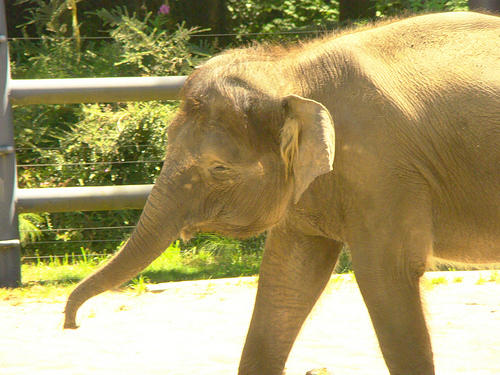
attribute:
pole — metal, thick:
[0, 3, 23, 285]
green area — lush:
[5, 2, 468, 291]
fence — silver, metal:
[0, 3, 184, 288]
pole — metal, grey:
[74, 62, 139, 110]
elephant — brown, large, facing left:
[62, 11, 499, 373]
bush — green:
[17, 51, 202, 265]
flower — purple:
[112, 7, 226, 51]